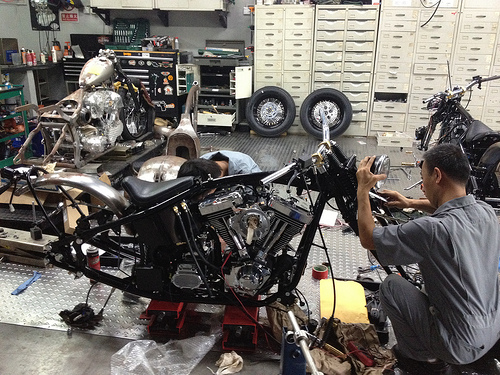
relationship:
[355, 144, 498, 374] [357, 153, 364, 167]
man has finger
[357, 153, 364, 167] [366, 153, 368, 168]
finger has finger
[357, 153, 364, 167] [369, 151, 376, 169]
finger has finger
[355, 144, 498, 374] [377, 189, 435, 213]
man has arm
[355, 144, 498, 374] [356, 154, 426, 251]
man has arm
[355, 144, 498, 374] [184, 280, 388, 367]
man squatted on floor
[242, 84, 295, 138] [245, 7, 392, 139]
tire leaning against cabinet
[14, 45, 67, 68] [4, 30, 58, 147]
bottles sitting on shelf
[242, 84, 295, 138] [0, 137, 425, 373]
tire on floor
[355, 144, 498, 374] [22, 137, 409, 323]
man working on motorcycle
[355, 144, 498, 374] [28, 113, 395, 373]
man working on motorcycle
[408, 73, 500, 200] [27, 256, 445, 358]
motorcycle on floor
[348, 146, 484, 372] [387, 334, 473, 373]
man wearing shoes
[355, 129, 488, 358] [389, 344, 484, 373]
man wearing shoes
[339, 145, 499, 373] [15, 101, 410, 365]
man working on motorcycle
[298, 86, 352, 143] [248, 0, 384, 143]
tire leaning against cabinet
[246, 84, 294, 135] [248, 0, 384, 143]
tire leaning against cabinet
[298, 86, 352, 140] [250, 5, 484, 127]
tire leaning against cabinets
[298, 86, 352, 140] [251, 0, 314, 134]
tire beside cabinet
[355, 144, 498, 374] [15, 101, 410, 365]
man working on motorcycle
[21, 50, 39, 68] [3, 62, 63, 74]
bottles on counter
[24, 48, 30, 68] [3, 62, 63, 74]
can on counter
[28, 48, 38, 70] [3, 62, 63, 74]
can on counter